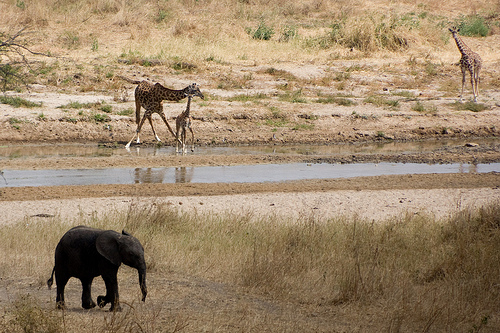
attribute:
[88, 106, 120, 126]
green grass — green , large clump 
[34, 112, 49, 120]
grass clump — green 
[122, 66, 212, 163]
giraffe — standing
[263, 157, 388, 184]
water — brown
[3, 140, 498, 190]
floor — muddy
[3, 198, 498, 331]
grass — dry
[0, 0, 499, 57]
grass — dry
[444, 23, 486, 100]
giraffe — standing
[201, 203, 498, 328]
grass — tall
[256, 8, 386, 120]
grass — dry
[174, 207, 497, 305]
branches — dried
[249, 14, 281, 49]
grass — green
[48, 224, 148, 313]
elephant — walking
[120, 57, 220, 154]
giraffe — standing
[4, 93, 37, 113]
grass — large clump , green 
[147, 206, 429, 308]
grass — dry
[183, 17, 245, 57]
grasses — brown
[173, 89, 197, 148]
giraffe — standing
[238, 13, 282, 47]
grass — large clump